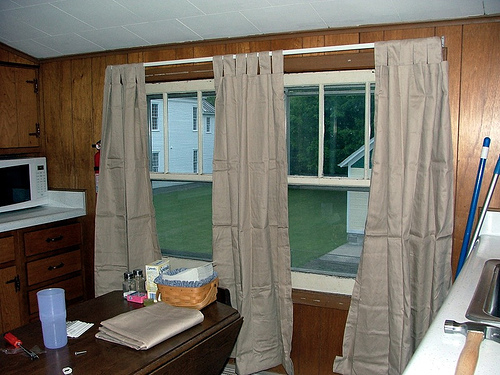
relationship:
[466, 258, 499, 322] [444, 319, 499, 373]
sink next to a hammer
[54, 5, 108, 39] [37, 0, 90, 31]
tile on a ceiling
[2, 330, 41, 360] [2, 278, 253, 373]
screwdriver on a table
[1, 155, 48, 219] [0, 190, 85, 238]
microwave on a counter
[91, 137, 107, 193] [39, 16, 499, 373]
extinguisher on wall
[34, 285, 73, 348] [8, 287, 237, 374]
cup on table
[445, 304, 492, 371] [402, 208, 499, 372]
hammer laying on counter